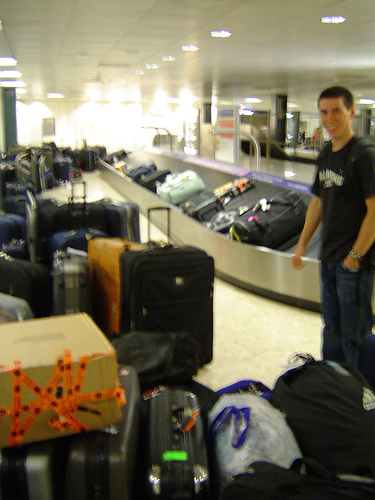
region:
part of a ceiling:
[125, 26, 179, 77]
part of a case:
[166, 438, 197, 468]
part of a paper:
[243, 422, 287, 465]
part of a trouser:
[306, 394, 333, 440]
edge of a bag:
[178, 435, 210, 473]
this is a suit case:
[119, 242, 219, 379]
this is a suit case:
[146, 390, 231, 499]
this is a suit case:
[217, 187, 310, 255]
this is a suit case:
[90, 233, 148, 326]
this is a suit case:
[54, 180, 142, 250]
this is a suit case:
[5, 257, 54, 318]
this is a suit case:
[41, 253, 94, 315]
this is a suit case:
[63, 360, 139, 497]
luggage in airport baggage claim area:
[0, 242, 70, 327]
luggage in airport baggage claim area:
[148, 387, 203, 484]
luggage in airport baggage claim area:
[12, 324, 119, 434]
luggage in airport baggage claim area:
[204, 379, 281, 473]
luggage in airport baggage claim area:
[277, 354, 370, 465]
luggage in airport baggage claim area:
[52, 247, 104, 307]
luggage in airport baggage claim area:
[156, 160, 211, 211]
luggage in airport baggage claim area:
[202, 173, 252, 205]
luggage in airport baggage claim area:
[235, 192, 294, 247]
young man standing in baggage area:
[304, 78, 370, 267]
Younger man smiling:
[316, 85, 363, 153]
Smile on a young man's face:
[293, 83, 373, 392]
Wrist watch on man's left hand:
[341, 248, 369, 268]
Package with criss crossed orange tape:
[0, 311, 133, 449]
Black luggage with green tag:
[138, 385, 211, 498]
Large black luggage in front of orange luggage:
[118, 205, 218, 372]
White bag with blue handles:
[205, 365, 312, 485]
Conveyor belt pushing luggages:
[92, 142, 322, 313]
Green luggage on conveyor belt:
[151, 166, 206, 205]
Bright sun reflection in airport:
[13, 78, 201, 153]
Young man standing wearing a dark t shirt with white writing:
[267, 89, 374, 367]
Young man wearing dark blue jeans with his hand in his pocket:
[286, 170, 373, 388]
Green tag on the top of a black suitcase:
[156, 413, 197, 463]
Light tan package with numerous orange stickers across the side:
[0, 319, 137, 436]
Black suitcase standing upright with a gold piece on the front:
[108, 199, 230, 367]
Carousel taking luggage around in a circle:
[136, 133, 289, 260]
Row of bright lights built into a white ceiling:
[1, 52, 29, 104]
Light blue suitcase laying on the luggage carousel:
[148, 163, 203, 207]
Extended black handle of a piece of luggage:
[118, 194, 181, 244]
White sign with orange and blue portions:
[204, 99, 243, 159]